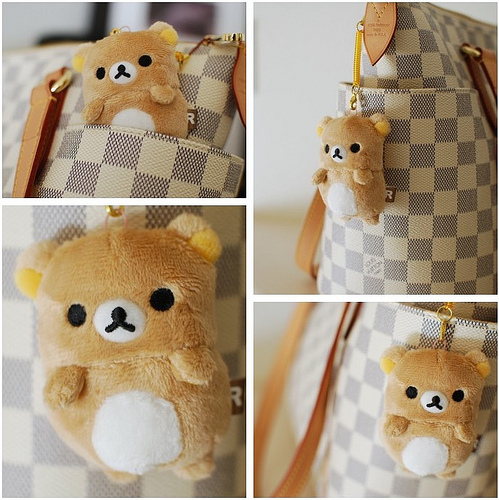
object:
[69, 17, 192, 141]
bear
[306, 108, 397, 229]
bear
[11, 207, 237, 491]
bear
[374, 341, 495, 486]
bear